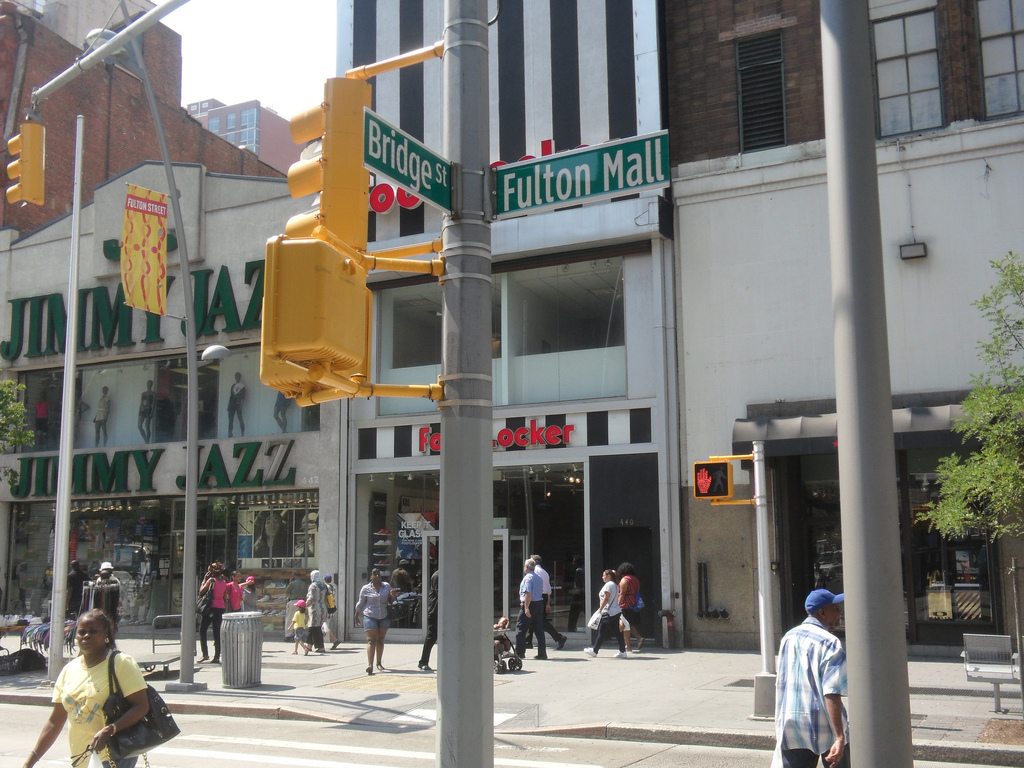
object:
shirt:
[52, 652, 151, 768]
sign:
[362, 104, 454, 217]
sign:
[486, 128, 675, 226]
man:
[772, 588, 852, 767]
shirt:
[773, 616, 848, 753]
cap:
[805, 589, 848, 616]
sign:
[7, 437, 303, 500]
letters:
[562, 423, 576, 444]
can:
[219, 610, 266, 690]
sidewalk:
[98, 622, 569, 724]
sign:
[0, 256, 272, 364]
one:
[136, 379, 158, 443]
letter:
[417, 426, 432, 453]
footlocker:
[418, 418, 576, 454]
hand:
[695, 467, 712, 494]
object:
[691, 453, 755, 507]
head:
[804, 589, 845, 630]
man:
[514, 558, 548, 660]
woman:
[584, 568, 629, 660]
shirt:
[354, 581, 394, 619]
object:
[98, 650, 189, 768]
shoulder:
[86, 649, 148, 673]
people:
[352, 567, 400, 675]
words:
[598, 136, 667, 192]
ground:
[400, 613, 753, 763]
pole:
[748, 438, 783, 725]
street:
[621, 658, 799, 764]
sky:
[206, 22, 354, 90]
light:
[258, 41, 449, 408]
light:
[4, 121, 45, 206]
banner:
[120, 181, 171, 319]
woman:
[616, 562, 645, 653]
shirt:
[205, 577, 227, 609]